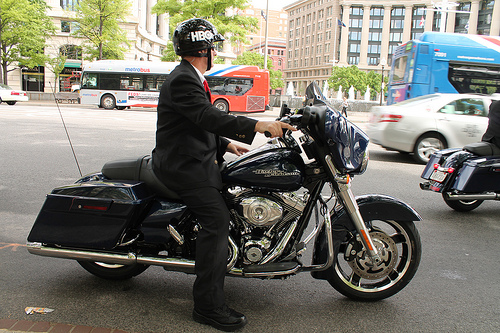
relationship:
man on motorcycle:
[148, 21, 293, 327] [21, 60, 421, 303]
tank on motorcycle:
[224, 143, 306, 192] [21, 60, 421, 303]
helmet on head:
[173, 20, 219, 51] [176, 12, 225, 77]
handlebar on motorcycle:
[262, 100, 305, 138] [26, 83, 420, 302]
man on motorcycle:
[148, 21, 293, 333] [77, 137, 407, 264]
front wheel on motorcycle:
[324, 216, 421, 302] [21, 60, 421, 303]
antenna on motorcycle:
[43, 77, 86, 177] [21, 60, 421, 303]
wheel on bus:
[98, 92, 118, 108] [77, 60, 269, 115]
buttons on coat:
[232, 126, 247, 142] [151, 61, 261, 189]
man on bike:
[148, 21, 293, 327] [24, 82, 421, 303]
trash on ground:
[24, 303, 57, 318] [0, 103, 499, 332]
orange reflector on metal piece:
[359, 226, 373, 252] [338, 184, 382, 264]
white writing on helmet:
[187, 29, 213, 45] [170, 17, 221, 54]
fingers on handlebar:
[265, 119, 297, 139] [262, 100, 305, 138]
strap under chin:
[200, 46, 210, 71] [208, 58, 213, 68]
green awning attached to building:
[59, 59, 84, 69] [39, 0, 96, 100]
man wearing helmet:
[148, 21, 293, 333] [175, 20, 222, 55]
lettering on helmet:
[190, 29, 213, 41] [171, 17, 226, 56]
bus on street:
[77, 60, 269, 115] [2, 95, 499, 331]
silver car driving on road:
[360, 81, 483, 166] [5, 104, 155, 209]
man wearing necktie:
[148, 21, 293, 327] [203, 78, 216, 105]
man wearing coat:
[148, 21, 293, 327] [151, 59, 261, 192]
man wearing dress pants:
[148, 21, 293, 333] [152, 155, 273, 331]